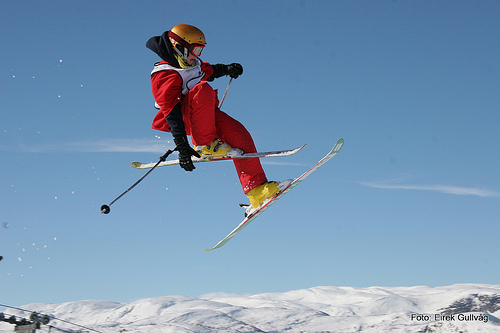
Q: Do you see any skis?
A: Yes, there are skis.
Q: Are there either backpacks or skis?
A: Yes, there are skis.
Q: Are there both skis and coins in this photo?
A: No, there are skis but no coins.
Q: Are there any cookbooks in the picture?
A: No, there are no cookbooks.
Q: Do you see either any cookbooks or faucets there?
A: No, there are no cookbooks or faucets.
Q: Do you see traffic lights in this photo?
A: No, there are no traffic lights.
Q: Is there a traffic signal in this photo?
A: No, there are no traffic lights.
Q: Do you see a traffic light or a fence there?
A: No, there are no traffic lights or fences.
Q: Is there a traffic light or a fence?
A: No, there are no traffic lights or fences.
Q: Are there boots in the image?
A: Yes, there are boots.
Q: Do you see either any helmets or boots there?
A: Yes, there are boots.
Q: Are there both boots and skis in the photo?
A: Yes, there are both boots and skis.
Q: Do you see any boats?
A: No, there are no boats.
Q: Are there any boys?
A: No, there are no boys.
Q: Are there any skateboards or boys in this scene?
A: No, there are no boys or skateboards.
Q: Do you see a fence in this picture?
A: No, there are no fences.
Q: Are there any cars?
A: No, there are no cars.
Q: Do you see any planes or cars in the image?
A: No, there are no cars or planes.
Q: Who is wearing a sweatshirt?
A: The skier is wearing a sweatshirt.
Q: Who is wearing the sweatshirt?
A: The skier is wearing a sweatshirt.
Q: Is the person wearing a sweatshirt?
A: Yes, the skier is wearing a sweatshirt.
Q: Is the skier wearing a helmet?
A: No, the skier is wearing a sweatshirt.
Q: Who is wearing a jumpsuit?
A: The skier is wearing a jumpsuit.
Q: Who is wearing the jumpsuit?
A: The skier is wearing a jumpsuit.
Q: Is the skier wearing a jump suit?
A: Yes, the skier is wearing a jump suit.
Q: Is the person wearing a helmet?
A: No, the skier is wearing a jump suit.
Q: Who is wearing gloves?
A: The skier is wearing gloves.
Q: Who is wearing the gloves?
A: The skier is wearing gloves.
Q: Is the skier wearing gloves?
A: Yes, the skier is wearing gloves.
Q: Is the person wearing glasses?
A: No, the skier is wearing gloves.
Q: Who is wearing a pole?
A: The skier is wearing a pole.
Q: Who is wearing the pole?
A: The skier is wearing a pole.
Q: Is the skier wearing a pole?
A: Yes, the skier is wearing a pole.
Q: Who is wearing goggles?
A: The skier is wearing goggles.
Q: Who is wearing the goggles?
A: The skier is wearing goggles.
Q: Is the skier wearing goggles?
A: Yes, the skier is wearing goggles.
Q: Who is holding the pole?
A: The skier is holding the pole.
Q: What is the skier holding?
A: The skier is holding the pole.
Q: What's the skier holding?
A: The skier is holding the pole.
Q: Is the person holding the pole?
A: Yes, the skier is holding the pole.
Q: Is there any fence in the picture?
A: No, there are no fences.